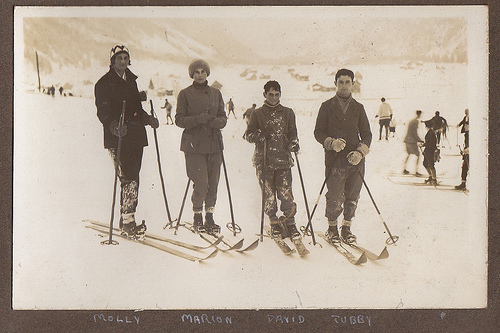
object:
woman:
[175, 59, 228, 232]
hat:
[188, 58, 210, 78]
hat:
[109, 44, 131, 65]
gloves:
[330, 138, 345, 152]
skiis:
[82, 218, 224, 263]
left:
[10, 5, 236, 312]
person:
[161, 98, 175, 125]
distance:
[35, 28, 422, 125]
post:
[35, 51, 41, 91]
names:
[180, 313, 231, 325]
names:
[266, 313, 305, 324]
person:
[94, 43, 160, 238]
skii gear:
[94, 69, 154, 215]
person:
[374, 97, 394, 140]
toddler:
[389, 119, 396, 138]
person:
[242, 79, 300, 239]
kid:
[313, 68, 372, 245]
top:
[376, 102, 395, 119]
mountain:
[26, 16, 467, 75]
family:
[92, 40, 373, 245]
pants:
[321, 155, 365, 221]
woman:
[403, 110, 424, 177]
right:
[321, 20, 459, 255]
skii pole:
[148, 99, 171, 222]